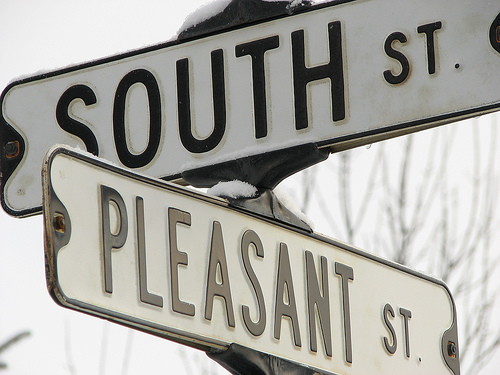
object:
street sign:
[14, 0, 467, 363]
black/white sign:
[0, 6, 500, 218]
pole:
[173, 5, 337, 41]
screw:
[48, 209, 70, 240]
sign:
[42, 144, 460, 374]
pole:
[226, 165, 324, 235]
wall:
[2, 4, 498, 373]